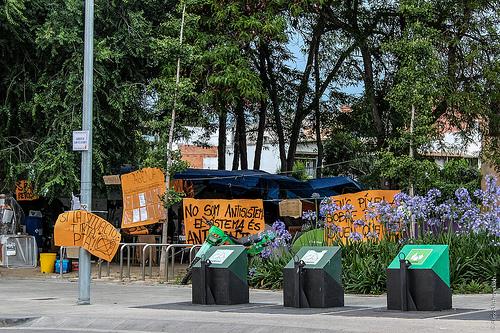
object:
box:
[390, 249, 454, 307]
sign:
[323, 189, 400, 245]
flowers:
[246, 188, 499, 244]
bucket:
[39, 253, 54, 272]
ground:
[2, 295, 493, 331]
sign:
[183, 196, 267, 239]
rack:
[125, 242, 158, 280]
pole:
[80, 3, 94, 298]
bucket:
[193, 242, 256, 303]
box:
[284, 248, 342, 307]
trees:
[20, 15, 463, 192]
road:
[53, 284, 484, 329]